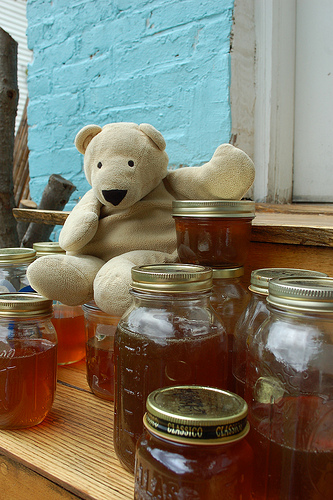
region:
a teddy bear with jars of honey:
[0, 117, 329, 498]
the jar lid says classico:
[142, 386, 250, 445]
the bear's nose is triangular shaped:
[99, 187, 129, 206]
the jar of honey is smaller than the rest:
[170, 195, 258, 263]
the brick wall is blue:
[23, 0, 231, 229]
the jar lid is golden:
[128, 263, 215, 296]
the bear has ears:
[74, 121, 166, 153]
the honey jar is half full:
[248, 275, 332, 497]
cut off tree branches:
[0, 23, 76, 257]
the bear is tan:
[28, 119, 258, 312]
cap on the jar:
[131, 261, 209, 289]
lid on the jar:
[153, 386, 229, 428]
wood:
[52, 413, 105, 460]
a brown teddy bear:
[85, 144, 181, 261]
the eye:
[92, 155, 113, 169]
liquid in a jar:
[13, 352, 59, 409]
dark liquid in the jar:
[131, 337, 155, 388]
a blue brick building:
[67, 56, 194, 116]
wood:
[266, 197, 315, 226]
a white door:
[296, 78, 331, 158]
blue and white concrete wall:
[30, 10, 260, 120]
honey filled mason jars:
[0, 304, 332, 498]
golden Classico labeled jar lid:
[139, 384, 258, 444]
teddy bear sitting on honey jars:
[26, 115, 270, 327]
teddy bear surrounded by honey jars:
[11, 101, 299, 323]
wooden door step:
[257, 167, 332, 261]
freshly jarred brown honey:
[117, 344, 222, 378]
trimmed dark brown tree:
[0, 15, 76, 210]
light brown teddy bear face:
[73, 120, 168, 209]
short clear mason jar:
[167, 196, 262, 267]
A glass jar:
[133, 384, 256, 499]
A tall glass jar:
[249, 273, 332, 490]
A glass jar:
[235, 267, 323, 368]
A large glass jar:
[110, 258, 228, 464]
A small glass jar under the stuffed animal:
[76, 293, 130, 403]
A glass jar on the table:
[1, 291, 61, 435]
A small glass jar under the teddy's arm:
[169, 142, 257, 266]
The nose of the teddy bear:
[95, 187, 132, 206]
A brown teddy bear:
[23, 122, 251, 318]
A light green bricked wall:
[44, 11, 219, 117]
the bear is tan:
[113, 222, 154, 257]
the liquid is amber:
[17, 384, 38, 399]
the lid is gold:
[180, 401, 208, 430]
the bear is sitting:
[84, 230, 148, 281]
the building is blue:
[153, 76, 195, 113]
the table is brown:
[61, 411, 90, 455]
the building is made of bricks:
[72, 45, 125, 80]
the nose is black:
[100, 186, 131, 207]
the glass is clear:
[283, 334, 319, 385]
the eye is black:
[92, 156, 110, 174]